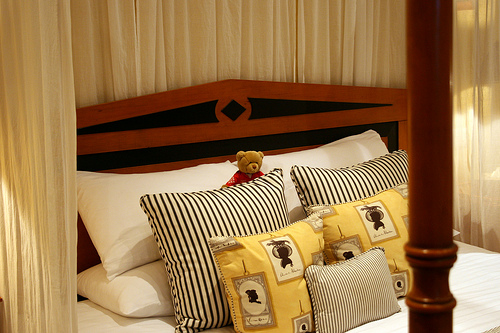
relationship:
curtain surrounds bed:
[0, 0, 495, 333] [73, 73, 499, 331]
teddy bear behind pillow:
[218, 149, 275, 190] [140, 151, 413, 333]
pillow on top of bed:
[140, 151, 413, 333] [73, 73, 499, 331]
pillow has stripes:
[140, 151, 413, 333] [160, 199, 212, 266]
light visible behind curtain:
[457, 106, 496, 222] [0, 0, 495, 333]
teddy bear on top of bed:
[218, 149, 275, 190] [73, 73, 499, 331]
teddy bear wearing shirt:
[218, 149, 275, 190] [226, 172, 265, 186]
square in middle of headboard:
[218, 98, 246, 125] [73, 76, 414, 171]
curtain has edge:
[0, 0, 495, 333] [63, 5, 80, 332]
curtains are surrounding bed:
[0, 0, 495, 333] [73, 73, 499, 331]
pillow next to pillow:
[210, 210, 323, 331] [76, 155, 256, 252]